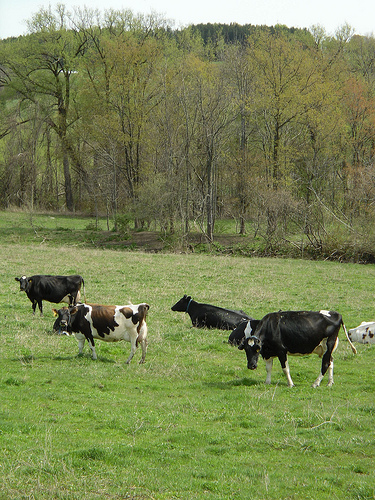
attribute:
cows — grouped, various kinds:
[14, 272, 374, 392]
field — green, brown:
[2, 212, 374, 499]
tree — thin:
[200, 91, 242, 245]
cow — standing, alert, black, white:
[15, 272, 86, 317]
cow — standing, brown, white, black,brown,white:
[52, 301, 151, 367]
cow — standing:
[236, 309, 359, 390]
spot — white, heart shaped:
[247, 337, 255, 348]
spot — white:
[317, 309, 331, 319]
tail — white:
[341, 323, 359, 358]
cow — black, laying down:
[170, 292, 255, 331]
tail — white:
[81, 281, 89, 305]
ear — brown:
[51, 308, 60, 320]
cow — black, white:
[226, 319, 266, 351]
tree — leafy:
[237, 43, 346, 240]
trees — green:
[1, 1, 374, 239]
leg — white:
[123, 331, 140, 370]